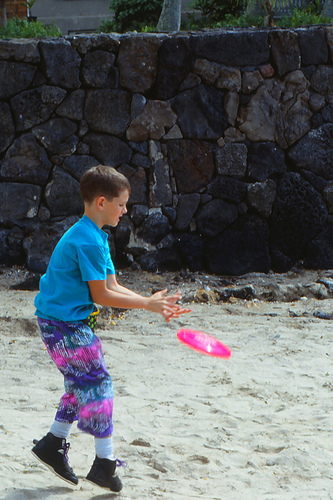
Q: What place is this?
A: It is a beach.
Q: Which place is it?
A: It is a beach.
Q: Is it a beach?
A: Yes, it is a beach.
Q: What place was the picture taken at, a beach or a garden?
A: It was taken at a beach.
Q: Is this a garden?
A: No, it is a beach.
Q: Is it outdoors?
A: Yes, it is outdoors.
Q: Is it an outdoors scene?
A: Yes, it is outdoors.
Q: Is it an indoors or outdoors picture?
A: It is outdoors.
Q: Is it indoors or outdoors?
A: It is outdoors.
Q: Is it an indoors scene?
A: No, it is outdoors.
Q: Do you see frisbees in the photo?
A: Yes, there is a frisbee.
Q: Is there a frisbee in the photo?
A: Yes, there is a frisbee.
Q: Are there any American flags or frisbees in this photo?
A: Yes, there is a frisbee.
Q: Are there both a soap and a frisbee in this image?
A: No, there is a frisbee but no soaps.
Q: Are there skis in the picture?
A: No, there are no skis.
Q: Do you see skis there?
A: No, there are no skis.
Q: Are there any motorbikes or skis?
A: No, there are no skis or motorbikes.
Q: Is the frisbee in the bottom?
A: Yes, the frisbee is in the bottom of the image.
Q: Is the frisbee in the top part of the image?
A: No, the frisbee is in the bottom of the image.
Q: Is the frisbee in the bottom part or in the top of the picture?
A: The frisbee is in the bottom of the image.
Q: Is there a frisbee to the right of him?
A: Yes, there is a frisbee to the right of the boy.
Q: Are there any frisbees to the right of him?
A: Yes, there is a frisbee to the right of the boy.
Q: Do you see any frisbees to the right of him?
A: Yes, there is a frisbee to the right of the boy.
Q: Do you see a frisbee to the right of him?
A: Yes, there is a frisbee to the right of the boy.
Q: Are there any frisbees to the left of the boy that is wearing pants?
A: No, the frisbee is to the right of the boy.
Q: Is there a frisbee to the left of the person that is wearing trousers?
A: No, the frisbee is to the right of the boy.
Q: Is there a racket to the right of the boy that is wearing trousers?
A: No, there is a frisbee to the right of the boy.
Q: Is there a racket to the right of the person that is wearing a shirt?
A: No, there is a frisbee to the right of the boy.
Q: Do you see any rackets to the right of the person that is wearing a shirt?
A: No, there is a frisbee to the right of the boy.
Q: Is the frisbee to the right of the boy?
A: Yes, the frisbee is to the right of the boy.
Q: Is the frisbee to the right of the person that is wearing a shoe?
A: Yes, the frisbee is to the right of the boy.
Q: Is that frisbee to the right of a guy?
A: No, the frisbee is to the right of the boy.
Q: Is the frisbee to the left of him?
A: No, the frisbee is to the right of a boy.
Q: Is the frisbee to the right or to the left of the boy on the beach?
A: The frisbee is to the right of the boy.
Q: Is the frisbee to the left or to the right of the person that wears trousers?
A: The frisbee is to the right of the boy.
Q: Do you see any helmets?
A: No, there are no helmets.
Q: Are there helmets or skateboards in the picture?
A: No, there are no helmets or skateboards.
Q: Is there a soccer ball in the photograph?
A: No, there are no soccer balls.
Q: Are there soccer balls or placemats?
A: No, there are no soccer balls or placemats.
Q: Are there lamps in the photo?
A: No, there are no lamps.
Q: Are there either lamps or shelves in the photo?
A: No, there are no lamps or shelves.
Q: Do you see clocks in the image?
A: No, there are no clocks.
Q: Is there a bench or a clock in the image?
A: No, there are no clocks or benches.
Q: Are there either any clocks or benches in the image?
A: No, there are no clocks or benches.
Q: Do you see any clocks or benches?
A: No, there are no clocks or benches.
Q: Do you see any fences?
A: No, there are no fences.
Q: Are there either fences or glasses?
A: No, there are no fences or glasses.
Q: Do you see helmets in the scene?
A: No, there are no helmets.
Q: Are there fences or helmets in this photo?
A: No, there are no helmets or fences.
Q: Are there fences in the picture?
A: No, there are no fences.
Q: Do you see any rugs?
A: No, there are no rugs.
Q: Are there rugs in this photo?
A: No, there are no rugs.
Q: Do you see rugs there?
A: No, there are no rugs.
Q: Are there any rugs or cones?
A: No, there are no rugs or cones.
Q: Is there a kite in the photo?
A: No, there are no kites.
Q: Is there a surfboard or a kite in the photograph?
A: No, there are no kites or surfboards.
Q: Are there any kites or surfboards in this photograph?
A: No, there are no kites or surfboards.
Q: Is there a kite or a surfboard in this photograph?
A: No, there are no kites or surfboards.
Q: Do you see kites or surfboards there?
A: No, there are no kites or surfboards.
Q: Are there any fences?
A: No, there are no fences.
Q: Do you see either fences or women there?
A: No, there are no fences or women.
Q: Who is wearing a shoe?
A: The boy is wearing a shoe.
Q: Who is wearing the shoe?
A: The boy is wearing a shoe.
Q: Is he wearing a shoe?
A: Yes, the boy is wearing a shoe.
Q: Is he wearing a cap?
A: No, the boy is wearing a shoe.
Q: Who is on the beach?
A: The boy is on the beach.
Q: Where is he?
A: The boy is on the beach.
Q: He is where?
A: The boy is on the beach.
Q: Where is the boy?
A: The boy is on the beach.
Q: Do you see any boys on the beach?
A: Yes, there is a boy on the beach.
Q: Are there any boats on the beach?
A: No, there is a boy on the beach.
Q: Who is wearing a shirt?
A: The boy is wearing a shirt.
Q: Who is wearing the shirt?
A: The boy is wearing a shirt.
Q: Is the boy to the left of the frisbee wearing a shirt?
A: Yes, the boy is wearing a shirt.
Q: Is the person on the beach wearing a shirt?
A: Yes, the boy is wearing a shirt.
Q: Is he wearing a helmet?
A: No, the boy is wearing a shirt.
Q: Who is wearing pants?
A: The boy is wearing pants.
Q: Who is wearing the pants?
A: The boy is wearing pants.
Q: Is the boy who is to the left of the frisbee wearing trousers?
A: Yes, the boy is wearing trousers.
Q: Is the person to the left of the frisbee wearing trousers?
A: Yes, the boy is wearing trousers.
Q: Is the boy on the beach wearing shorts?
A: No, the boy is wearing trousers.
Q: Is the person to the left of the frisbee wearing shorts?
A: No, the boy is wearing trousers.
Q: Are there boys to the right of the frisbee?
A: No, the boy is to the left of the frisbee.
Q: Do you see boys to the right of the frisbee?
A: No, the boy is to the left of the frisbee.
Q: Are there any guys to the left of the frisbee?
A: No, there is a boy to the left of the frisbee.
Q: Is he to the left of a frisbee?
A: Yes, the boy is to the left of a frisbee.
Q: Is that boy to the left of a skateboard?
A: No, the boy is to the left of a frisbee.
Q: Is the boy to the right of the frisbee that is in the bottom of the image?
A: No, the boy is to the left of the frisbee.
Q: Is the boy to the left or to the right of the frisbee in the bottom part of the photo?
A: The boy is to the left of the frisbee.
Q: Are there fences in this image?
A: No, there are no fences.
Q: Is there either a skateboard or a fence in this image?
A: No, there are no fences or skateboards.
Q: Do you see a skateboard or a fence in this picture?
A: No, there are no fences or skateboards.